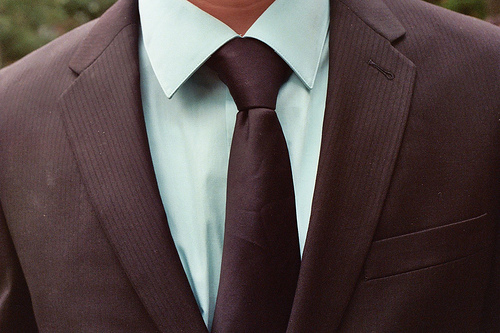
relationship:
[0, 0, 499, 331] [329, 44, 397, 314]
coat has stripe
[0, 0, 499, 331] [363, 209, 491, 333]
coat has pocket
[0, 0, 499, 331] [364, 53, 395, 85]
coat has part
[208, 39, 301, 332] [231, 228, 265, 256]
tie has wrinkle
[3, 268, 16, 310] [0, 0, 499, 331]
wrinkle on coat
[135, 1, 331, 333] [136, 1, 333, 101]
shirt has collar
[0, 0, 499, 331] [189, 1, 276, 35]
coat has neck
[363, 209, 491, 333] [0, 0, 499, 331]
pocket on front of coat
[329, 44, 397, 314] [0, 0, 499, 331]
stripe on front of coat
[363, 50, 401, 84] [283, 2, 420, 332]
button hole on top of lapel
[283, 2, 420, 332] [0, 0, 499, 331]
lapel on front of coat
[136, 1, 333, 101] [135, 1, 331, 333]
collar on top of shirt